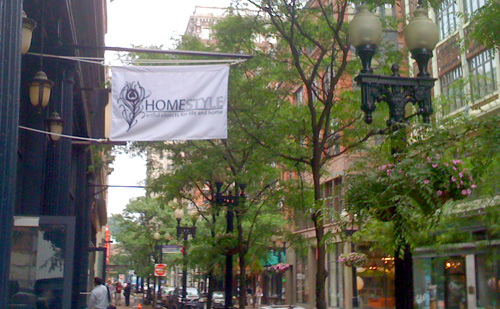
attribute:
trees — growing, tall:
[221, 32, 457, 277]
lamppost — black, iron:
[357, 56, 429, 305]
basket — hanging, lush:
[330, 249, 369, 268]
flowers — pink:
[348, 257, 356, 262]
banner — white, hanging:
[104, 63, 231, 146]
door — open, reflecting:
[81, 251, 106, 304]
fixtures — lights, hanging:
[27, 71, 71, 147]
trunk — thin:
[305, 124, 332, 308]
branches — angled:
[254, 132, 377, 165]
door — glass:
[18, 215, 74, 306]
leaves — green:
[242, 110, 286, 173]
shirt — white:
[89, 286, 109, 309]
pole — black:
[365, 78, 433, 303]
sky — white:
[118, 6, 172, 34]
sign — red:
[152, 262, 169, 277]